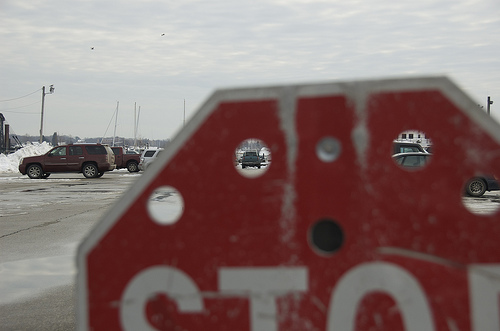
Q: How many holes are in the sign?
A: Six.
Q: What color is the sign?
A: Red.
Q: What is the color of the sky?
A: Gray.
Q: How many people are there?
A: None.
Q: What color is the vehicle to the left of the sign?
A: Red.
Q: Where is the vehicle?
A: A parking lot.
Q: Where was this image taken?
A: Parking lot.